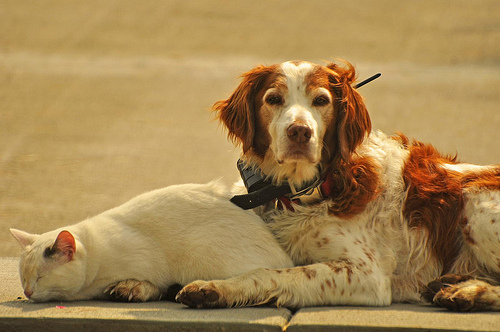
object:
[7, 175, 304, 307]
cat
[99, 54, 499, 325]
dog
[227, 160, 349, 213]
collar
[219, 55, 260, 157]
ears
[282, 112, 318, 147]
nose